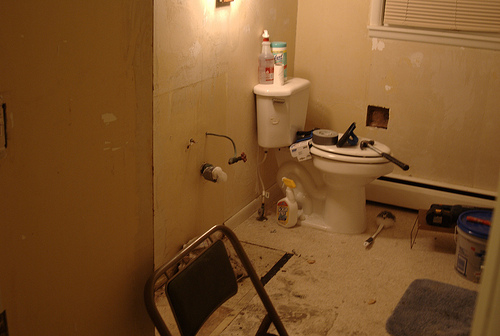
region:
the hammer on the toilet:
[353, 133, 409, 187]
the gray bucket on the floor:
[451, 208, 496, 280]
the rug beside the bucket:
[385, 273, 475, 335]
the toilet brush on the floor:
[354, 205, 402, 257]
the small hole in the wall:
[357, 99, 402, 131]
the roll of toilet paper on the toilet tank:
[262, 59, 290, 88]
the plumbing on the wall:
[170, 143, 262, 197]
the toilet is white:
[248, 66, 399, 240]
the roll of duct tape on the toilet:
[303, 123, 336, 148]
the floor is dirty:
[275, 244, 357, 333]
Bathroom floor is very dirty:
[161, 214, 335, 333]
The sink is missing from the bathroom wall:
[157, 66, 249, 275]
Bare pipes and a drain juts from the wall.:
[175, 119, 253, 187]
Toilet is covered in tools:
[247, 31, 421, 243]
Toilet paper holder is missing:
[362, 103, 392, 130]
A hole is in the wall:
[363, 103, 395, 130]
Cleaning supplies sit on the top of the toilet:
[251, 23, 287, 85]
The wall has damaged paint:
[366, 38, 498, 184]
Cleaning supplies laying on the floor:
[271, 171, 403, 249]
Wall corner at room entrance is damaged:
[148, 1, 158, 334]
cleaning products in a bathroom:
[236, 15, 304, 97]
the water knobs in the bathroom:
[177, 132, 257, 192]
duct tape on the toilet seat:
[308, 115, 341, 152]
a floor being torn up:
[258, 230, 344, 311]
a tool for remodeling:
[336, 112, 416, 191]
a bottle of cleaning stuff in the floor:
[263, 164, 315, 236]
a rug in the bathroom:
[375, 243, 491, 333]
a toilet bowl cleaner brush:
[360, 198, 399, 265]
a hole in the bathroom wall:
[353, 83, 405, 142]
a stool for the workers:
[118, 223, 295, 334]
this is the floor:
[331, 263, 390, 295]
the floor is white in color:
[315, 246, 350, 286]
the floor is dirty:
[282, 286, 306, 317]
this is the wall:
[177, 39, 220, 60]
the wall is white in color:
[315, 50, 359, 70]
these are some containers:
[255, 29, 302, 91]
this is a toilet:
[258, 83, 390, 236]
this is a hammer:
[359, 133, 414, 169]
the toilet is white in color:
[271, 87, 297, 114]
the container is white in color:
[286, 204, 299, 216]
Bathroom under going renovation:
[118, 12, 494, 329]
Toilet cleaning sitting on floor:
[271, 173, 302, 229]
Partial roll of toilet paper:
[269, 60, 286, 89]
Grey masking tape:
[312, 123, 339, 150]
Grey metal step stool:
[136, 222, 298, 334]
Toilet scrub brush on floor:
[363, 205, 398, 257]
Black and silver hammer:
[361, 135, 411, 175]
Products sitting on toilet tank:
[256, 26, 314, 151]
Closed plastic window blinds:
[380, 1, 498, 34]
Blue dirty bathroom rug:
[384, 272, 484, 334]